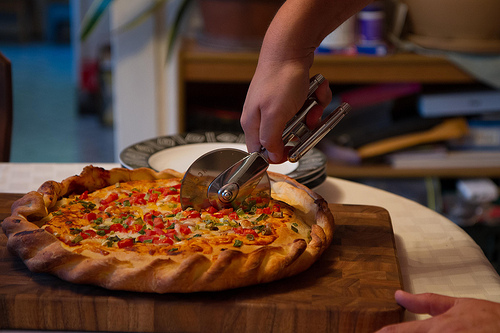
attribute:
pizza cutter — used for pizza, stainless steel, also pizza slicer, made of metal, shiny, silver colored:
[178, 96, 321, 213]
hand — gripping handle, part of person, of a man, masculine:
[233, 62, 331, 163]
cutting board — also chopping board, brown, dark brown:
[1, 196, 407, 333]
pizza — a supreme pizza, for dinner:
[10, 167, 337, 296]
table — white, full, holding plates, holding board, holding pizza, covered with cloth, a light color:
[3, 158, 500, 299]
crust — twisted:
[46, 248, 246, 291]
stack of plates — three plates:
[111, 135, 332, 188]